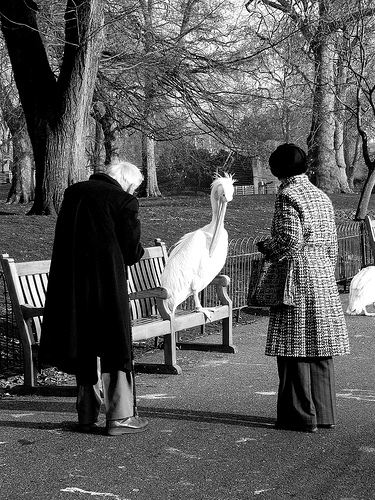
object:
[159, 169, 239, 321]
bird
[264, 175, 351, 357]
coat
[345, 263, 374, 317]
bird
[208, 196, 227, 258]
beak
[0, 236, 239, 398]
bench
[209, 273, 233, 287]
armrest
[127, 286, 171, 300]
armrest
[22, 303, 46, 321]
armrest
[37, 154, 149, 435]
man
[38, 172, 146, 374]
coat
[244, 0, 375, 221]
tree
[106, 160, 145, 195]
hair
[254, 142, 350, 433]
people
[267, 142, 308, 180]
hat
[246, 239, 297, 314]
bag